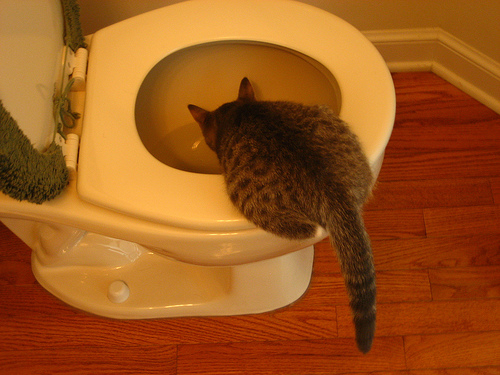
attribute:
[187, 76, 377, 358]
cat — black, brown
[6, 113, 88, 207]
seat cover — green, fuzzy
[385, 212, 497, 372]
floor — wood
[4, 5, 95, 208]
cover — green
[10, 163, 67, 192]
cover — green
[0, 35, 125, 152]
lid — up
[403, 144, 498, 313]
wood — light brown